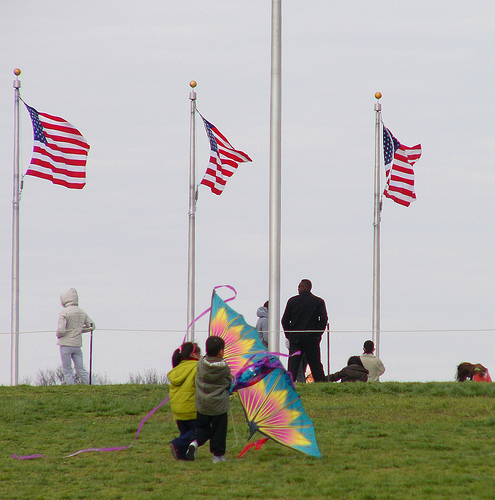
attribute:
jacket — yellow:
[199, 360, 228, 430]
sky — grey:
[2, 1, 493, 384]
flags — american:
[18, 96, 420, 207]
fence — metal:
[80, 321, 467, 385]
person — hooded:
[52, 283, 98, 386]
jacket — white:
[53, 285, 96, 350]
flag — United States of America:
[380, 123, 422, 209]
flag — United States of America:
[18, 97, 88, 193]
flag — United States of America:
[194, 112, 250, 193]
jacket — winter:
[197, 357, 233, 414]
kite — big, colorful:
[210, 280, 330, 459]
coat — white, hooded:
[57, 292, 92, 350]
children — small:
[132, 285, 342, 462]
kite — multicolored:
[180, 284, 320, 459]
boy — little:
[183, 334, 229, 461]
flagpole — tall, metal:
[265, 15, 309, 370]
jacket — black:
[281, 295, 326, 339]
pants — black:
[287, 330, 323, 379]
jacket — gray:
[172, 283, 257, 418]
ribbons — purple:
[231, 344, 306, 392]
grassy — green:
[10, 377, 493, 491]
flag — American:
[22, 96, 92, 197]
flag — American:
[194, 102, 256, 196]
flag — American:
[382, 124, 426, 205]